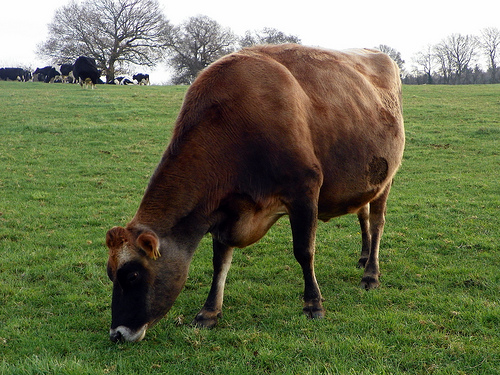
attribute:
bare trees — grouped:
[94, 25, 183, 79]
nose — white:
[107, 322, 147, 347]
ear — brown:
[135, 229, 156, 254]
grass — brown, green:
[8, 77, 496, 369]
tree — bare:
[39, 17, 199, 79]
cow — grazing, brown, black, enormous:
[97, 38, 407, 352]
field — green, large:
[1, 85, 498, 374]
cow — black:
[93, 36, 428, 339]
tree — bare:
[168, 20, 225, 76]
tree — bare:
[46, 1, 174, 83]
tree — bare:
[402, 29, 499, 81]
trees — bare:
[332, 10, 488, 122]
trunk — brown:
[106, 71, 120, 86]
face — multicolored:
[109, 237, 154, 343]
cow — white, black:
[34, 41, 454, 367]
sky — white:
[0, 0, 499, 86]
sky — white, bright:
[227, 5, 452, 50]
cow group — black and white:
[2, 54, 152, 86]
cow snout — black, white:
[108, 290, 150, 351]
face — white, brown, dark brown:
[98, 221, 188, 344]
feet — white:
[192, 257, 237, 318]